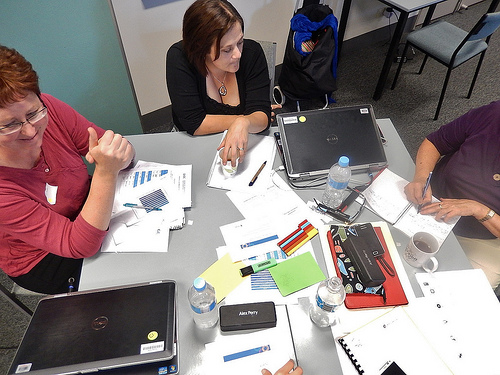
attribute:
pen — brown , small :
[244, 155, 271, 194]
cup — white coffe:
[404, 230, 437, 272]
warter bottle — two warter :
[308, 274, 345, 327]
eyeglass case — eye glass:
[214, 305, 279, 332]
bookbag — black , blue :
[264, 10, 378, 120]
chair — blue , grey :
[397, 12, 497, 125]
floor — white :
[352, 56, 498, 122]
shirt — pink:
[2, 96, 112, 284]